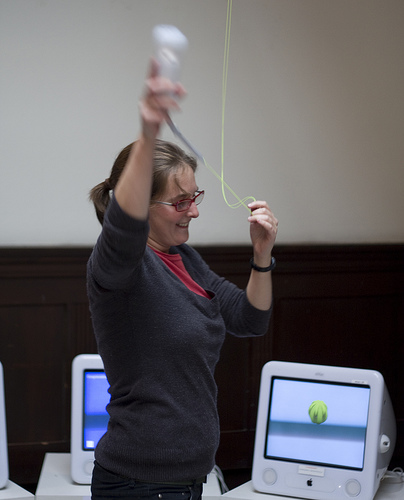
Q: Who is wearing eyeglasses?
A: The woman.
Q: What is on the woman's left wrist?
A: A watch.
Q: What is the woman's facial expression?
A: Smiling.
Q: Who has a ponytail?
A: The woman.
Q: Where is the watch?
A: On the woman's left wrist.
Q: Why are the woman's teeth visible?
A: She is smiling.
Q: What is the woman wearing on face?
A: Glasses.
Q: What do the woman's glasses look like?
A: Red.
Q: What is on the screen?
A: Screensaver.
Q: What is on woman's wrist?
A: Watch.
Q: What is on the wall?
A: Paneling.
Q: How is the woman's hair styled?
A: Ponytail.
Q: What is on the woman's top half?
A: Shirt.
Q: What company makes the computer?
A: Apple.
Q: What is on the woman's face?
A: Glasses.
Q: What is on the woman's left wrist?
A: Watch.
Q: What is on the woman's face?
A: Glasses.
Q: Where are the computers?
A: Behind the woman.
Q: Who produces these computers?
A: Apple.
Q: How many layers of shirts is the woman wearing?
A: 2.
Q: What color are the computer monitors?
A: White.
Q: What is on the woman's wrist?
A: Watch.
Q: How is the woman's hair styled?
A: Ponytail.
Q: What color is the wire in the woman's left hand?
A: Green.